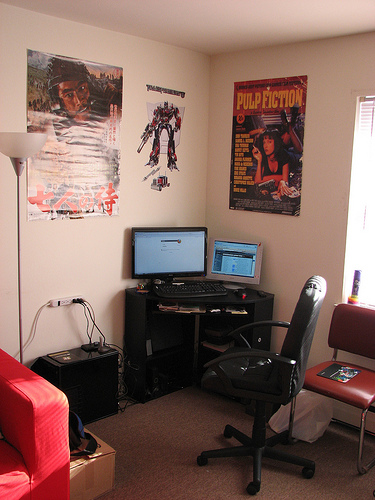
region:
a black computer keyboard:
[153, 279, 227, 299]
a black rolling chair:
[195, 275, 327, 493]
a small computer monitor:
[203, 235, 266, 289]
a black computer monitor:
[129, 227, 208, 281]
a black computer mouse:
[235, 287, 247, 299]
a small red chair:
[292, 303, 372, 473]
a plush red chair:
[0, 344, 71, 497]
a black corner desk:
[121, 277, 274, 403]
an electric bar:
[15, 294, 84, 362]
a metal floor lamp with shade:
[0, 130, 49, 371]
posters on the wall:
[17, 66, 310, 216]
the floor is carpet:
[155, 418, 181, 462]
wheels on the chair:
[183, 446, 293, 497]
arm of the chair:
[186, 347, 274, 360]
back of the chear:
[270, 264, 308, 392]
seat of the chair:
[196, 355, 282, 390]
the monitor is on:
[119, 224, 211, 275]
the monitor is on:
[207, 235, 254, 276]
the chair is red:
[321, 361, 372, 391]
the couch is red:
[14, 398, 52, 434]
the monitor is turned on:
[130, 225, 205, 278]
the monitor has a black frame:
[130, 227, 207, 277]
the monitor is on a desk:
[130, 224, 198, 281]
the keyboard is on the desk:
[151, 279, 229, 304]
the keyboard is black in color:
[155, 287, 233, 304]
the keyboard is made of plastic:
[162, 285, 238, 305]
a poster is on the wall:
[229, 70, 306, 216]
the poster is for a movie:
[232, 72, 304, 217]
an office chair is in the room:
[204, 278, 321, 485]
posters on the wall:
[2, 56, 299, 225]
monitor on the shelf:
[90, 217, 195, 284]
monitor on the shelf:
[214, 234, 260, 290]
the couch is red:
[7, 374, 94, 483]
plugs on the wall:
[39, 283, 106, 316]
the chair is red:
[317, 288, 372, 416]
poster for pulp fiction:
[198, 23, 304, 208]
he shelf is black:
[130, 275, 259, 389]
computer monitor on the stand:
[128, 222, 208, 275]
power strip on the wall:
[48, 298, 84, 305]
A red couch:
[0, 348, 85, 489]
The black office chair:
[193, 274, 335, 488]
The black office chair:
[187, 271, 332, 485]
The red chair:
[302, 295, 372, 473]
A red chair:
[295, 295, 371, 471]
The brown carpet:
[82, 382, 369, 493]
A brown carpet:
[84, 380, 369, 498]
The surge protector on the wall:
[35, 287, 96, 319]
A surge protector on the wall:
[45, 290, 92, 309]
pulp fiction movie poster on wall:
[218, 65, 318, 217]